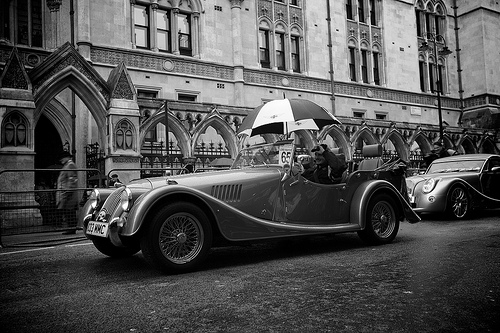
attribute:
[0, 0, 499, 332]
picture — black, white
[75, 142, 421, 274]
car — antique, old fashioned, convertible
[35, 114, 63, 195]
doorway — arched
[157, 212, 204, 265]
rims — metallic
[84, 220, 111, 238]
license plate — black, white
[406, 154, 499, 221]
car — parked, vintage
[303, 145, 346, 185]
man — waving, driving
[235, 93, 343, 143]
umbrella — black, white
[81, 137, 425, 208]
fence — metal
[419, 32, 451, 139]
street lamp — old fashioned